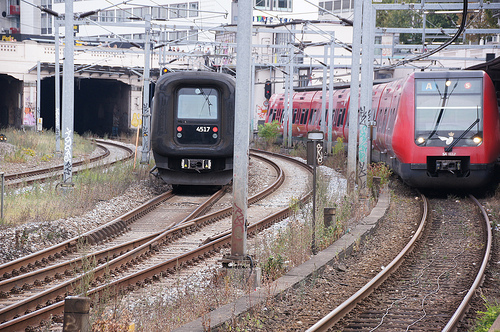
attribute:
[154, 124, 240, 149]
head lights — round, red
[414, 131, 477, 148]
head lights — white, round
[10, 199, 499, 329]
tracks — train 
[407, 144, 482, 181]
guard — black, metal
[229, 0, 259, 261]
pole — gray, metal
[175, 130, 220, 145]
circles — gray, small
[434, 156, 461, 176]
cattle guard — black, silver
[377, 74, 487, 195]
train — red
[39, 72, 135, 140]
train tunnel — dark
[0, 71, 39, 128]
train tunnel — dark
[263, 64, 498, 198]
train — red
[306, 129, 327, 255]
pole — brown, metal